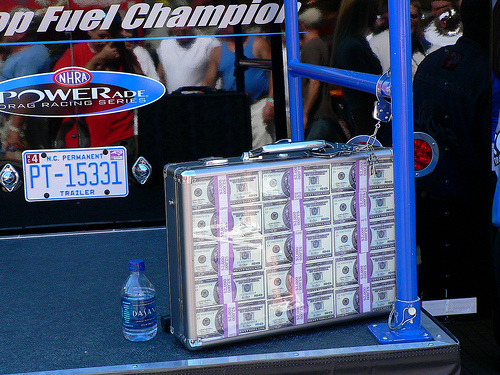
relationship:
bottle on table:
[121, 258, 157, 343] [1, 223, 461, 373]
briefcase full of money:
[164, 139, 407, 351] [186, 156, 403, 340]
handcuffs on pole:
[348, 69, 392, 149] [369, 0, 431, 347]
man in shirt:
[155, 14, 223, 94] [155, 35, 222, 95]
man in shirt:
[202, 17, 275, 149] [218, 36, 268, 102]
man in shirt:
[2, 8, 51, 162] [0, 43, 52, 119]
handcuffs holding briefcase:
[348, 69, 392, 149] [164, 139, 407, 351]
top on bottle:
[128, 257, 147, 271] [121, 258, 157, 343]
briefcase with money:
[164, 139, 407, 351] [186, 156, 403, 340]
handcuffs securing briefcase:
[348, 69, 392, 149] [164, 139, 407, 351]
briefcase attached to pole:
[164, 139, 407, 351] [369, 0, 431, 347]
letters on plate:
[26, 152, 122, 196] [21, 146, 129, 202]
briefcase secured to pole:
[164, 139, 407, 351] [369, 0, 431, 347]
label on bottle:
[121, 291, 158, 329] [121, 258, 157, 343]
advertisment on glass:
[3, 66, 166, 122] [3, 2, 302, 236]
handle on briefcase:
[248, 140, 326, 159] [164, 139, 407, 351]